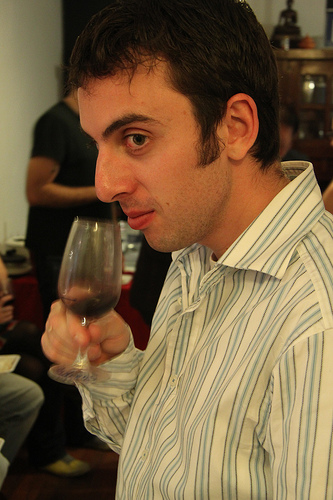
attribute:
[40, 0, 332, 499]
man —  blue striped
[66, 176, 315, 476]
shirt — white, gray 